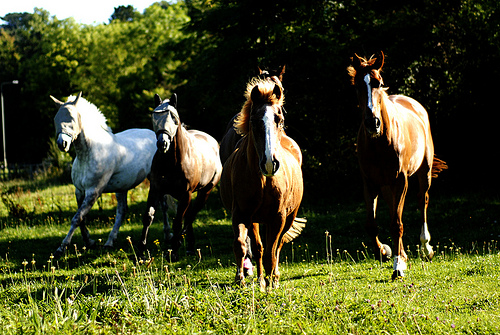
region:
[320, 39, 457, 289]
this is the first horse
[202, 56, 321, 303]
this is the second horse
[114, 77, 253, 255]
this is the third horse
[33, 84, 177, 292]
this is the 4th horse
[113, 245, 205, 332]
these are brown weeds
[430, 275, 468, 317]
this is the grass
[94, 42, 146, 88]
these are green leaves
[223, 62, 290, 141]
this is a mane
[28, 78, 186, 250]
this is a white horse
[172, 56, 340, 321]
this is a brown horse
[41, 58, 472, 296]
four horses running on grass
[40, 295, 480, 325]
green grass in a field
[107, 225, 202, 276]
wild flowers in the grass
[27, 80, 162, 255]
white horse running on grass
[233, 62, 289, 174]
face of a brown horse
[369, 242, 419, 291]
hooves of a horse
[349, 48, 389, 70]
ears of a horse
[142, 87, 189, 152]
horse with a mask on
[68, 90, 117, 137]
mane of a white horse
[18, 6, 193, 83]
green leaves on trees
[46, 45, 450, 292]
five horses running a field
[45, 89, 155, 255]
a white horse running with other horses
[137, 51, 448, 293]
Four brown horses running on in a pasture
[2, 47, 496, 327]
five horse on a ranch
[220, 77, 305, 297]
a brown horse with a white nose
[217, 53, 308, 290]
a brown horse in front of another horse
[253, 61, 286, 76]
the ears of a horse behind another horse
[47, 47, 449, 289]
show horses exercising in a pasture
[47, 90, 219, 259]
a brown horse running beside a white horse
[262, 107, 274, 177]
white nose on a brown horse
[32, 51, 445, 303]
A herd of horses.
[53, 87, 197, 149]
Two horses wearing masks.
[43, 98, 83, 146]
A sack on its head.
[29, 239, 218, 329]
Weeds in the grass.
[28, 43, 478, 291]
Horses running through a grass field.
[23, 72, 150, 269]
A white horse.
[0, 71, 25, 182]
A street light in the distance.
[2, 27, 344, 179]
Trees behind the horses.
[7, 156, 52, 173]
A white pikett fence.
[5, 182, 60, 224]
Long blades of grass.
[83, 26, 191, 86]
green leaves on trees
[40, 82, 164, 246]
white horse with covered face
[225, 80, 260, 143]
mane on horse neck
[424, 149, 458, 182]
tip of horse tail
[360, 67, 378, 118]
white patch on nose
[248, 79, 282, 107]
ears on horse head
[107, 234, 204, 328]
tall weeds on ground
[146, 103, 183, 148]
cover on horse face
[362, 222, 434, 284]
hooves of running horse